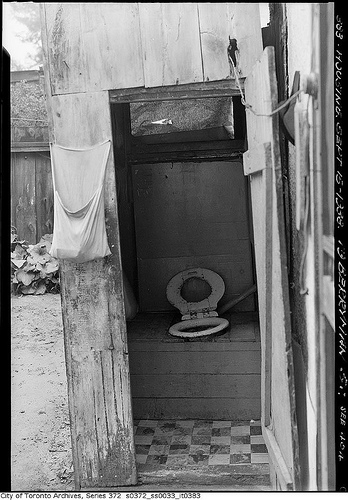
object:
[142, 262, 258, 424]
base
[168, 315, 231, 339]
seat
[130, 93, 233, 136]
label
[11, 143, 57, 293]
fence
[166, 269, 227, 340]
seat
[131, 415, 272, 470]
checkered floor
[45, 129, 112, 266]
bag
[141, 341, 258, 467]
outhouse floor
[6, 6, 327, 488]
photo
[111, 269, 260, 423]
dirty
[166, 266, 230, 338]
commode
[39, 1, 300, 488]
outhouse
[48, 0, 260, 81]
board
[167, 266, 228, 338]
toilet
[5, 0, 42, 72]
plants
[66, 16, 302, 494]
shed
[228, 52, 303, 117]
string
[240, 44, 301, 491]
door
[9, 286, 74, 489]
ground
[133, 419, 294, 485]
floor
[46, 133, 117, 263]
white cloth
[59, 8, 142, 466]
wall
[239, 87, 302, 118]
rope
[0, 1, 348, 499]
photo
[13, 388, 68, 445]
dirt